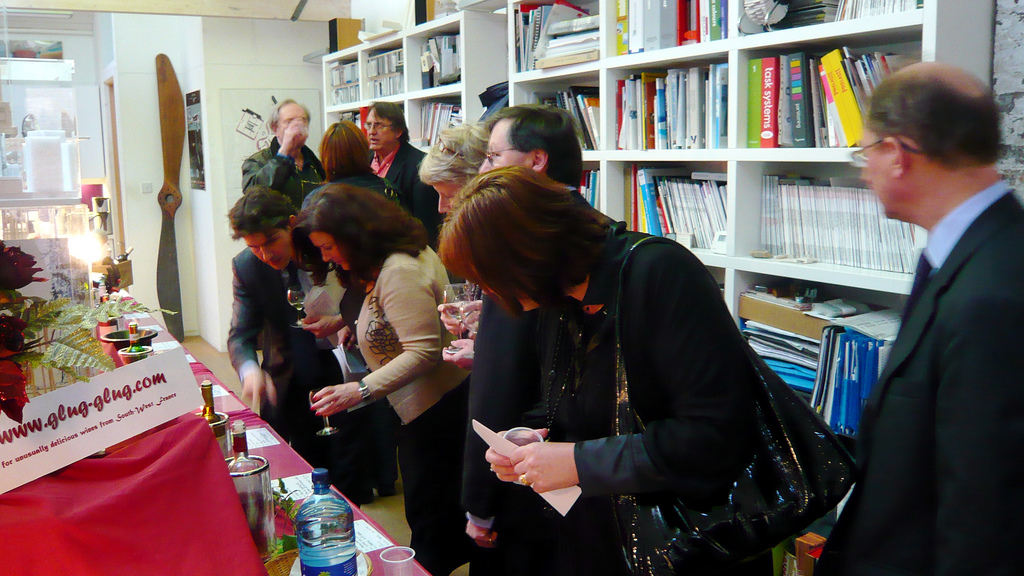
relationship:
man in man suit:
[810, 47, 1020, 572] [811, 180, 1022, 576]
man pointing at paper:
[227, 187, 363, 505] [224, 422, 282, 449]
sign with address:
[47, 58, 330, 454] [12, 369, 211, 476]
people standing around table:
[198, 67, 911, 532] [8, 271, 432, 570]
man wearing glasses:
[814, 63, 1022, 576] [813, 115, 921, 172]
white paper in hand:
[467, 415, 582, 521] [511, 437, 578, 486]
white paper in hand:
[467, 415, 582, 521] [487, 431, 516, 482]